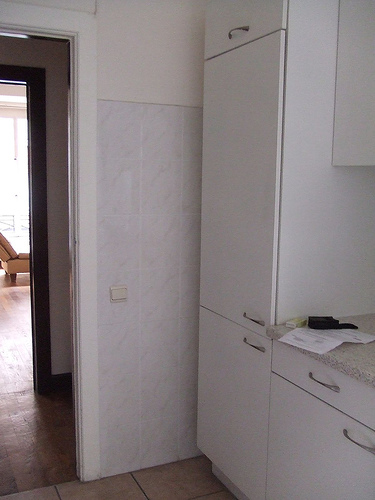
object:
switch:
[110, 282, 128, 302]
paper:
[276, 326, 374, 358]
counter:
[270, 322, 374, 390]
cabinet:
[197, 30, 287, 337]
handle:
[243, 308, 269, 330]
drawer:
[270, 338, 374, 431]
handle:
[308, 369, 339, 397]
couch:
[0, 232, 33, 284]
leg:
[10, 273, 18, 283]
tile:
[129, 457, 230, 499]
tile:
[57, 469, 150, 498]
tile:
[0, 484, 59, 496]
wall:
[96, 100, 203, 481]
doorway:
[1, 16, 89, 487]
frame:
[68, 32, 101, 482]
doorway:
[1, 60, 56, 393]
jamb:
[26, 82, 52, 398]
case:
[304, 312, 358, 329]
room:
[0, 85, 31, 390]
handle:
[226, 24, 248, 38]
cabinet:
[203, 0, 285, 61]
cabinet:
[195, 306, 271, 498]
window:
[1, 120, 27, 230]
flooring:
[2, 272, 33, 395]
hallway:
[0, 390, 76, 494]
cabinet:
[263, 371, 373, 498]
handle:
[341, 428, 374, 455]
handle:
[242, 337, 268, 355]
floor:
[2, 473, 234, 499]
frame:
[1, 1, 93, 40]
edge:
[271, 335, 374, 383]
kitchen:
[101, 1, 374, 496]